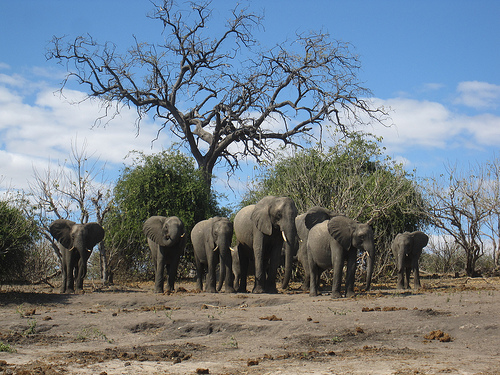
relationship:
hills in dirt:
[1, 302, 274, 360] [0, 274, 499, 374]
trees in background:
[0, 141, 436, 283] [1, 2, 499, 285]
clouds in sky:
[1, 57, 500, 256] [0, 0, 499, 271]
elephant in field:
[42, 208, 108, 296] [0, 274, 499, 374]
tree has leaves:
[101, 141, 232, 282] [104, 141, 238, 268]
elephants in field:
[45, 193, 432, 298] [0, 274, 499, 374]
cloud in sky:
[1, 85, 175, 173] [0, 0, 499, 271]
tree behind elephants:
[41, 0, 400, 215] [45, 193, 432, 298]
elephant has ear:
[42, 208, 108, 296] [46, 213, 77, 252]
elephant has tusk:
[228, 188, 304, 297] [277, 227, 289, 245]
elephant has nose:
[42, 208, 108, 296] [74, 236, 89, 280]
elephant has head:
[42, 208, 108, 296] [46, 215, 112, 262]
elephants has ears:
[45, 193, 432, 298] [43, 214, 108, 253]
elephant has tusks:
[228, 188, 304, 297] [278, 226, 306, 247]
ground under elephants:
[0, 274, 499, 374] [45, 193, 432, 298]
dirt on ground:
[0, 274, 499, 374] [7, 261, 496, 320]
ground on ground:
[0, 274, 499, 374] [7, 261, 496, 320]